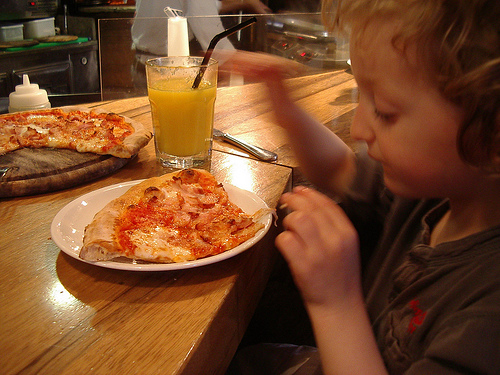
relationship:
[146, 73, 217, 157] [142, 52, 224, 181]
drink in glass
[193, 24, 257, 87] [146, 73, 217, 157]
straw in drink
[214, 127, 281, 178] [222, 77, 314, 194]
knife on table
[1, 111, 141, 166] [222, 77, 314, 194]
pizza on table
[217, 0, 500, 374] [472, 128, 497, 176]
boy wearing headphones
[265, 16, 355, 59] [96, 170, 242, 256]
oven for pizza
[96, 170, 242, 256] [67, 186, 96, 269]
pizza on plate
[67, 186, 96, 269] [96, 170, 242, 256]
plate under pizza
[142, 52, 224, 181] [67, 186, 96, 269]
glass behind plate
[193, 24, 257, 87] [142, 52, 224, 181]
straw in glass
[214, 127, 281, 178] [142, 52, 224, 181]
knife behind glass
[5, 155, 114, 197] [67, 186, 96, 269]
cutting board behind plate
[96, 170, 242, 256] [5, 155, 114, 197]
pizza on cutting board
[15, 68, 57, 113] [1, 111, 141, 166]
bottle behind pizza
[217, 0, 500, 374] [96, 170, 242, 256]
boy eating pizza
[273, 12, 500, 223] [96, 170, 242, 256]
boy eating pizza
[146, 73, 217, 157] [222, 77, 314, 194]
drink on table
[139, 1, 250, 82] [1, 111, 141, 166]
man making pizzas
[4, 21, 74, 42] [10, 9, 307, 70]
bins in background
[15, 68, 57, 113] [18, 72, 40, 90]
bottle has top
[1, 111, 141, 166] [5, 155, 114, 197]
pizza on cutting board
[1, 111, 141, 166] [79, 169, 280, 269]
pizza missing pizza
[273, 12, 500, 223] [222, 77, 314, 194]
boy at table